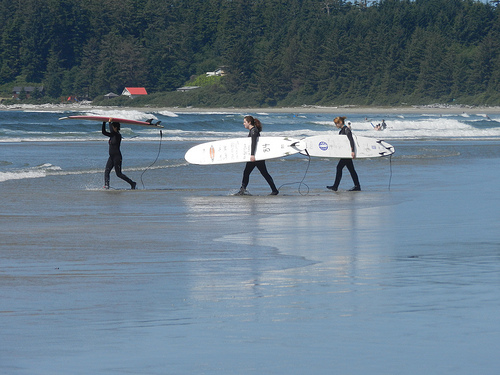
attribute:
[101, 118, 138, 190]
surfer — walking, black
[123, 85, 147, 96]
roof — red, orange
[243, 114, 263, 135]
surfers — woman, brown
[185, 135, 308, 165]
surfboards — white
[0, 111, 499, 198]
surfing — sport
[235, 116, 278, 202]
surfer — walking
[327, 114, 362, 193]
surfer — walking, girl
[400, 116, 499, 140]
waves — whitecapped, crashing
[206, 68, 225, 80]
building — white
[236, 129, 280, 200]
wetsuit — black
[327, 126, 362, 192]
wetsuit — black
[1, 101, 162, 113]
shoreline — rocky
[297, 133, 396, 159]
surfboard — white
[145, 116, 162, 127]
fin — black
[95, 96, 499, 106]
grass — green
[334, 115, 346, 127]
her hair — brown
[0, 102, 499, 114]
shoreline — rocky